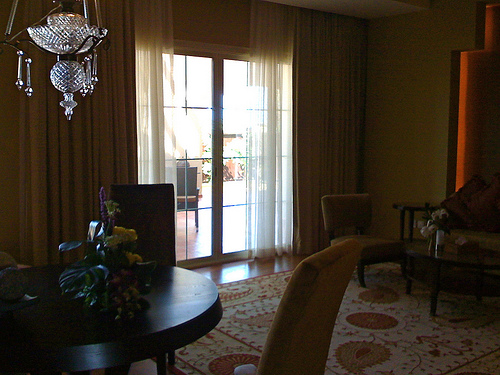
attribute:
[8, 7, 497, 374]
living area — nicely decorated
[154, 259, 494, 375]
rug — goldtone, large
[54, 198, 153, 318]
arrangement — floral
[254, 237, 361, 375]
chair — high backed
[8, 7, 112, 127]
chandelier — beautiful, crystal, clear, upholstered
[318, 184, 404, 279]
chair — brown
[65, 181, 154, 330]
flowers — colorful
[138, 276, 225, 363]
table — black, wooden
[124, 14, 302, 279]
curtains — drawn, white